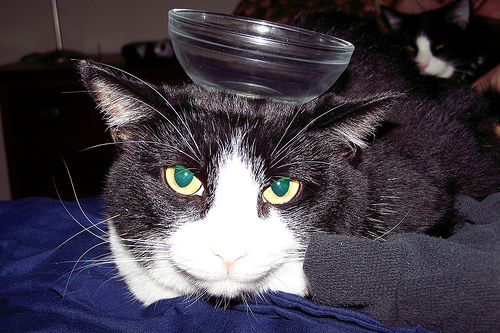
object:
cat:
[77, 2, 500, 308]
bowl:
[167, 8, 356, 105]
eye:
[159, 163, 304, 206]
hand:
[471, 66, 500, 95]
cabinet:
[0, 0, 178, 51]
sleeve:
[405, 8, 430, 17]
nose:
[207, 235, 253, 275]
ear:
[73, 57, 172, 142]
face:
[133, 119, 340, 263]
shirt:
[302, 192, 500, 332]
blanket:
[19, 202, 70, 264]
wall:
[24, 13, 68, 47]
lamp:
[119, 34, 174, 65]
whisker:
[36, 193, 162, 300]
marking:
[280, 266, 321, 292]